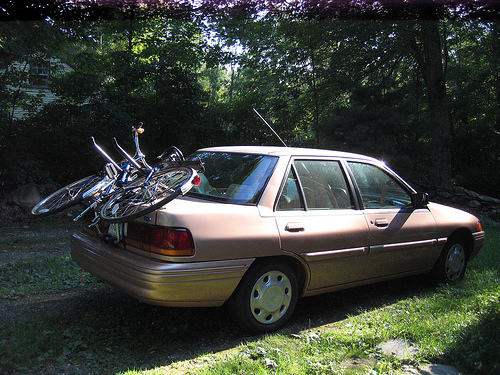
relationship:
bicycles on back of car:
[30, 120, 207, 228] [69, 145, 484, 333]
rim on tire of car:
[249, 269, 292, 323] [69, 145, 484, 333]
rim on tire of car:
[443, 243, 465, 281] [69, 145, 484, 333]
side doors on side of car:
[276, 155, 436, 291] [69, 145, 484, 333]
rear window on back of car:
[181, 150, 278, 206] [69, 145, 484, 333]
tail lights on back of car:
[82, 206, 194, 260] [69, 145, 484, 333]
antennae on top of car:
[251, 105, 290, 148] [69, 145, 484, 333]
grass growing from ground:
[4, 220, 499, 374] [1, 199, 497, 374]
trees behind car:
[0, 0, 499, 200] [69, 145, 484, 333]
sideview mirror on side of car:
[409, 191, 429, 207] [69, 145, 484, 333]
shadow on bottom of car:
[2, 275, 427, 374] [69, 145, 484, 333]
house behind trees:
[2, 37, 102, 128] [0, 0, 499, 200]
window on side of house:
[27, 56, 53, 91] [2, 37, 102, 128]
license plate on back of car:
[103, 220, 128, 237] [69, 145, 484, 333]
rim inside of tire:
[249, 269, 292, 323] [225, 256, 298, 332]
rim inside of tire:
[443, 243, 465, 281] [431, 237, 467, 284]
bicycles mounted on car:
[30, 120, 207, 228] [69, 145, 484, 333]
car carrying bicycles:
[69, 145, 484, 333] [30, 120, 207, 228]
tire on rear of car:
[225, 256, 298, 332] [69, 145, 484, 333]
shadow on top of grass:
[2, 275, 427, 374] [4, 220, 499, 374]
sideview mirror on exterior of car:
[409, 191, 429, 207] [69, 145, 484, 333]